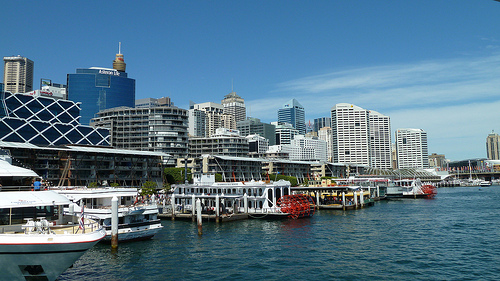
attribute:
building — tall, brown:
[3, 51, 34, 102]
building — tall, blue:
[19, 21, 453, 228]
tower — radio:
[112, 40, 126, 70]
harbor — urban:
[44, 97, 485, 219]